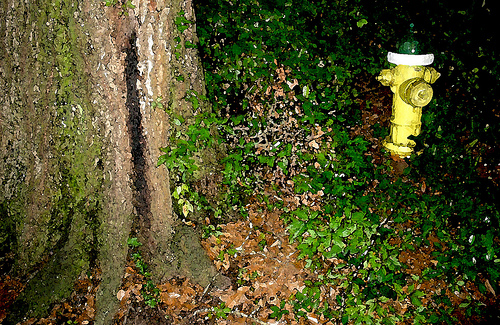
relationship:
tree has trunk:
[2, 0, 272, 323] [0, 3, 244, 216]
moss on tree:
[44, 3, 88, 202] [2, 0, 272, 323]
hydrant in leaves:
[373, 21, 442, 158] [194, 0, 498, 324]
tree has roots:
[2, 0, 272, 323] [0, 230, 235, 324]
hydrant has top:
[373, 21, 442, 158] [386, 29, 434, 66]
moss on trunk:
[44, 3, 88, 202] [0, 3, 244, 216]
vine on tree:
[128, 235, 159, 307] [2, 0, 272, 323]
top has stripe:
[386, 29, 434, 66] [385, 51, 436, 64]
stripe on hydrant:
[385, 51, 436, 64] [373, 21, 442, 158]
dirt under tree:
[120, 303, 176, 324] [2, 0, 272, 323]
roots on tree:
[0, 230, 235, 324] [2, 0, 272, 323]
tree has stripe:
[2, 0, 272, 323] [121, 35, 150, 220]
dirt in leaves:
[120, 303, 176, 324] [194, 0, 498, 324]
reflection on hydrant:
[411, 47, 415, 53] [373, 21, 442, 158]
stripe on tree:
[121, 35, 150, 220] [2, 0, 272, 323]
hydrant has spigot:
[373, 21, 442, 158] [403, 81, 434, 105]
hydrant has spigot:
[373, 21, 442, 158] [376, 71, 391, 86]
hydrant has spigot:
[373, 21, 442, 158] [427, 67, 442, 82]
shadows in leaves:
[360, 6, 499, 199] [194, 0, 498, 324]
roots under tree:
[0, 230, 235, 324] [2, 0, 272, 323]